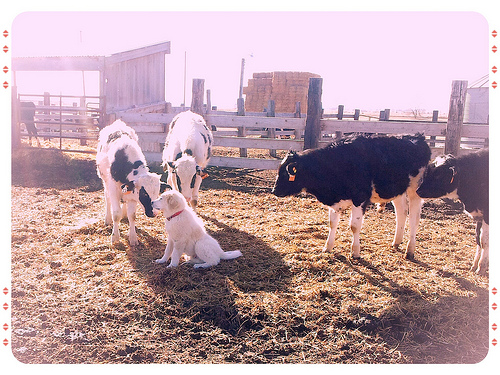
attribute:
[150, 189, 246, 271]
retriever — yellow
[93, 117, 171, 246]
cow — brown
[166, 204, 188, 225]
collar — red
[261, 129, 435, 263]
cow — black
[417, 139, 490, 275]
cow — white, black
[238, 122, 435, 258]
cow — black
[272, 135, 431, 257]
cow — black, white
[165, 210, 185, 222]
collar — red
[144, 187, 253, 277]
dog — white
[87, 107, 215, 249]
cows — white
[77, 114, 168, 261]
cow — white, black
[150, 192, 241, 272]
animal — many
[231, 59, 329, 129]
straw — large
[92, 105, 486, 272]
animals — many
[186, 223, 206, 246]
fur — white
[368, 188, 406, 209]
belly — white